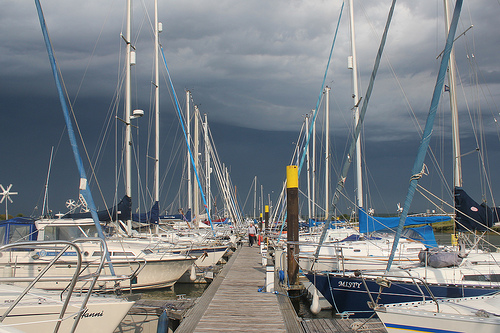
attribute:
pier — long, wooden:
[192, 247, 277, 330]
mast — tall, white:
[114, 0, 140, 230]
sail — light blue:
[383, 0, 461, 273]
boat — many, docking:
[0, 234, 137, 331]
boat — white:
[364, 289, 496, 330]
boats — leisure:
[37, 189, 235, 306]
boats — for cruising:
[0, 0, 199, 293]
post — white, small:
[258, 239, 265, 256]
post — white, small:
[258, 245, 269, 267]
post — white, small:
[262, 262, 277, 294]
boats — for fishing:
[261, 0, 498, 332]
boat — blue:
[287, 221, 489, 313]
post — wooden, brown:
[286, 163, 300, 285]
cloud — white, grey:
[3, 0, 497, 145]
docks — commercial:
[20, 180, 464, 329]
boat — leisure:
[10, 3, 227, 280]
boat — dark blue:
[294, 247, 496, 319]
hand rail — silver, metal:
[1, 237, 113, 331]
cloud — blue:
[4, 1, 484, 77]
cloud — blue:
[8, 45, 498, 150]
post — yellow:
[287, 163, 307, 283]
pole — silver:
[336, 0, 377, 231]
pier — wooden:
[173, 228, 381, 330]